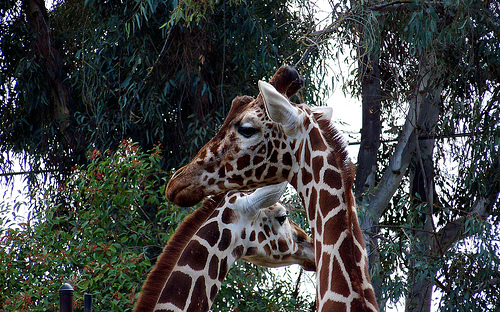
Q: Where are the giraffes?
A: Next to the trees.